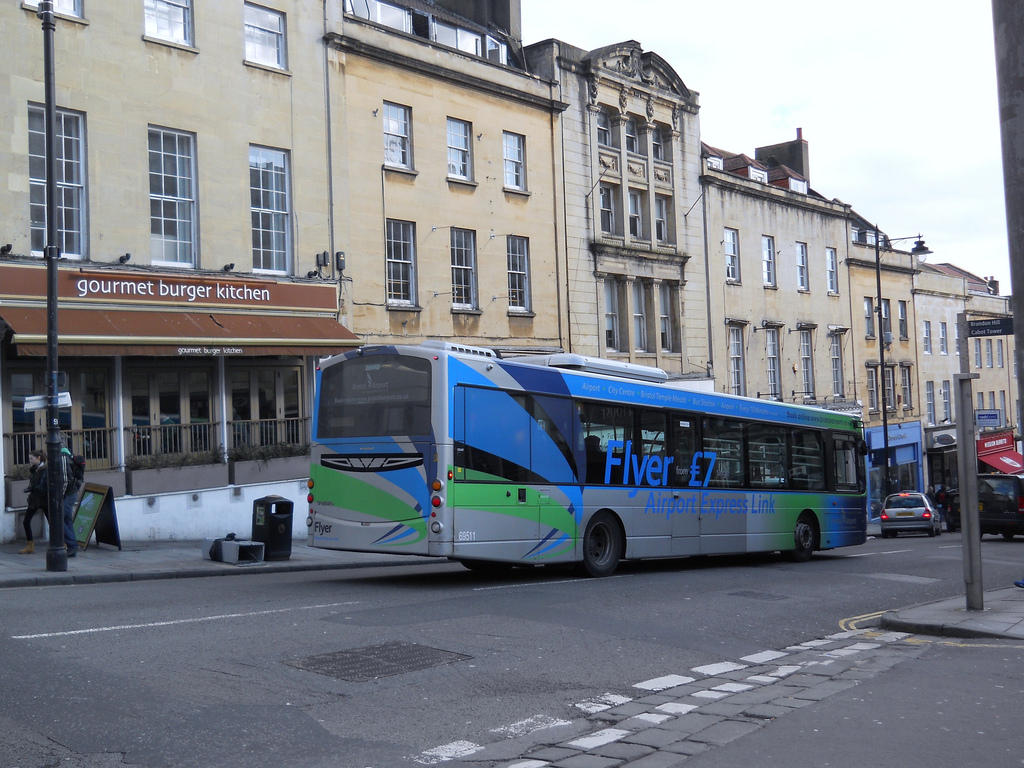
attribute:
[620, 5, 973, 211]
sky — white, cloudy, blue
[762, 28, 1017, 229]
sky — blue, white, cloudy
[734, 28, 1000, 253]
sky — cloudy, blue, white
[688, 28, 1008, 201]
sky — white, cloudy, blue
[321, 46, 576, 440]
building — tan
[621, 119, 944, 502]
building — tan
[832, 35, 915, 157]
sky — white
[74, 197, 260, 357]
sign — white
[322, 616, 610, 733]
street — grey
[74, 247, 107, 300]
letter — grey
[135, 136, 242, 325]
letter — grey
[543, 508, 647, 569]
tire — black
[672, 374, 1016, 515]
windshield — clear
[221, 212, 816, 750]
bus — blue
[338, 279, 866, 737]
cars — green